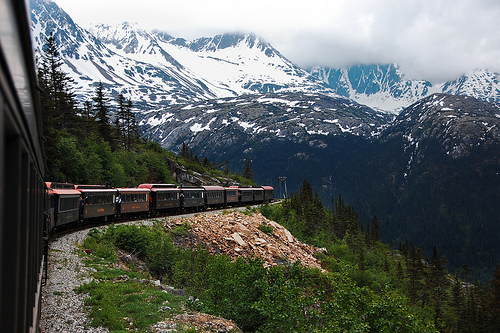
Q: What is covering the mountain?
A: Snow.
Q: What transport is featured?
A: A train.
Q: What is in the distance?
A: Mountains.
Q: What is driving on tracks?
A: A train.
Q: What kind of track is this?
A: Train track.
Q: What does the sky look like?
A: Grey.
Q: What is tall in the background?
A: Trees.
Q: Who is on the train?
A: People.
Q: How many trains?
A: 1.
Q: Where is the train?
A: On the track.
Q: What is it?
A: A train.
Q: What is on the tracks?
A: Train.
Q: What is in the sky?
A: Clouds.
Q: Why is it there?
A: Traveling.